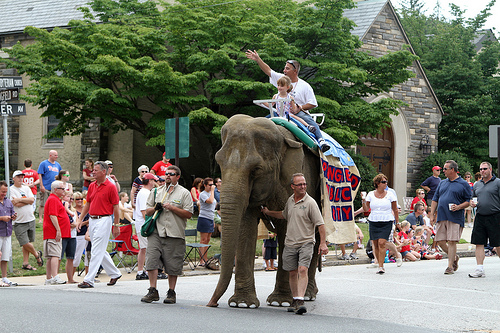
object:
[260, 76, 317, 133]
child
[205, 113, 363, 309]
elephant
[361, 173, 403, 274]
woman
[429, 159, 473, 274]
people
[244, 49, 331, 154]
man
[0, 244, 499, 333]
road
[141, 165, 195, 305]
trainer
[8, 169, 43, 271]
man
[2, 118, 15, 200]
pole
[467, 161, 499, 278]
people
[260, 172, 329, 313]
person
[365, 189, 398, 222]
blouse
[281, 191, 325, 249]
shirt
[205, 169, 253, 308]
trunk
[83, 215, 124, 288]
pants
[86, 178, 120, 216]
shirt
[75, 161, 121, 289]
guy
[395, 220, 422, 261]
kids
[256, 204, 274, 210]
curb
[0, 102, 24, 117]
signs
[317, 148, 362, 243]
sign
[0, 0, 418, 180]
tree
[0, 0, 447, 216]
building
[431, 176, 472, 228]
shirt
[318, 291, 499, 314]
line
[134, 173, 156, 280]
man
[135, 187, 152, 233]
top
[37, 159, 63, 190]
shirt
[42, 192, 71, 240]
shirt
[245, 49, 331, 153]
two people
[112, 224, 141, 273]
chair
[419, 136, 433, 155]
light